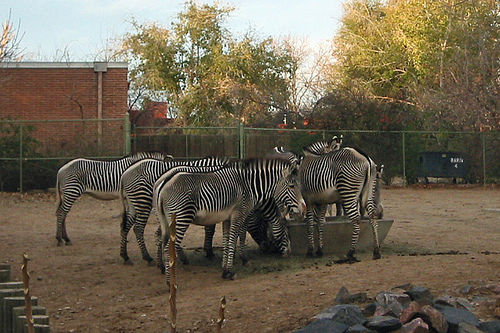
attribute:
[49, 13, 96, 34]
sky — blue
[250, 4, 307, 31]
clouds — white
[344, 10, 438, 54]
leaves — green, yellow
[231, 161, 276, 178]
mane — black, white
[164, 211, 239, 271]
legs — white, black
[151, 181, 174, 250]
tail — white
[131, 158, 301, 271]
zebra — one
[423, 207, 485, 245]
ground — brown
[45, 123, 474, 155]
fence — grey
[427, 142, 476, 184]
bin — blue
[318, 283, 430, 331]
rocks — grey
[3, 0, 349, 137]
sky — blue, daytime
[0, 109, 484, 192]
fence — chain link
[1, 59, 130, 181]
wall — brick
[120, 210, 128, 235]
tip — black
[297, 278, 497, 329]
rock pile — gray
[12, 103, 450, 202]
fence — chain link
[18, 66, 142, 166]
wall — red brick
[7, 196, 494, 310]
surface — dirt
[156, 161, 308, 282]
zebra — standing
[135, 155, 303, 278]
zebra — standing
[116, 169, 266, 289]
zebra — standing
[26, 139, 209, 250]
zebra — standing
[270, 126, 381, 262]
zebra — standing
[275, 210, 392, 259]
metal bin — metal 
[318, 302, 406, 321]
van — white